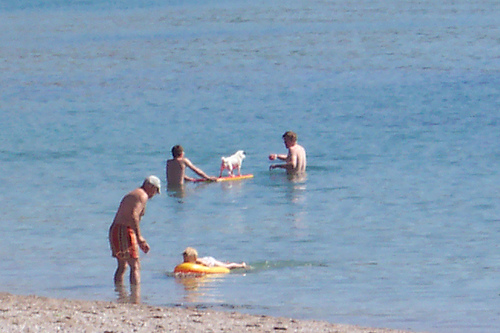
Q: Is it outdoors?
A: Yes, it is outdoors.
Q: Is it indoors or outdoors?
A: It is outdoors.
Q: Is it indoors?
A: No, it is outdoors.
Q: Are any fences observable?
A: No, there are no fences.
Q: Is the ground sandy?
A: Yes, the ground is sandy.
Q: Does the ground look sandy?
A: Yes, the ground is sandy.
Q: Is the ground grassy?
A: No, the ground is sandy.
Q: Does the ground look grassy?
A: No, the ground is sandy.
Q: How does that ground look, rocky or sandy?
A: The ground is sandy.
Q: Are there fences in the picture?
A: No, there are no fences.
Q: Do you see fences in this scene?
A: No, there are no fences.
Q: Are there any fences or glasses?
A: No, there are no fences or glasses.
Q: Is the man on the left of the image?
A: Yes, the man is on the left of the image.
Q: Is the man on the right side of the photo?
A: No, the man is on the left of the image.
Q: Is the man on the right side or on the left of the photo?
A: The man is on the left of the image.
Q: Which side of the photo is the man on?
A: The man is on the left of the image.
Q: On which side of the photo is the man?
A: The man is on the left of the image.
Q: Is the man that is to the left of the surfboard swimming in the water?
A: Yes, the man is swimming in the water.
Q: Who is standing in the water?
A: The man is standing in the water.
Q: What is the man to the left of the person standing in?
A: The man is standing in the water.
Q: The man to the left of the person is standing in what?
A: The man is standing in the water.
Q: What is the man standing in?
A: The man is standing in the water.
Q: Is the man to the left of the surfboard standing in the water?
A: Yes, the man is standing in the water.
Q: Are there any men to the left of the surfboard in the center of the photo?
A: Yes, there is a man to the left of the surfboard.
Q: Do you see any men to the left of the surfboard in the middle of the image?
A: Yes, there is a man to the left of the surfboard.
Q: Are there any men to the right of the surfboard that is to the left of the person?
A: No, the man is to the left of the surfboard.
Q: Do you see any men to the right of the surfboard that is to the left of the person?
A: No, the man is to the left of the surfboard.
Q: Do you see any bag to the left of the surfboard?
A: No, there is a man to the left of the surfboard.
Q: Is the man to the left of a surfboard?
A: Yes, the man is to the left of a surfboard.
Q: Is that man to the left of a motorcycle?
A: No, the man is to the left of a surfboard.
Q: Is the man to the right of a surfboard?
A: No, the man is to the left of a surfboard.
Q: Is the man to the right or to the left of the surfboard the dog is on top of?
A: The man is to the left of the surfboard.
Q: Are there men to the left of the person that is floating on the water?
A: Yes, there is a man to the left of the person.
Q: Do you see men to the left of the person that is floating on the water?
A: Yes, there is a man to the left of the person.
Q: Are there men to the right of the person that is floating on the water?
A: No, the man is to the left of the person.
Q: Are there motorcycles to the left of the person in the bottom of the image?
A: No, there is a man to the left of the person.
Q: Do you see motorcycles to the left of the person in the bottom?
A: No, there is a man to the left of the person.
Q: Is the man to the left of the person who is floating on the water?
A: Yes, the man is to the left of the person.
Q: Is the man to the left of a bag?
A: No, the man is to the left of the person.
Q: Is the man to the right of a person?
A: No, the man is to the left of a person.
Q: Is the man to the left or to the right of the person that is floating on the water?
A: The man is to the left of the person.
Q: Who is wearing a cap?
A: The man is wearing a cap.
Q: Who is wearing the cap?
A: The man is wearing a cap.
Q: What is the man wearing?
A: The man is wearing a cap.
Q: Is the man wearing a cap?
A: Yes, the man is wearing a cap.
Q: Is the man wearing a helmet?
A: No, the man is wearing a cap.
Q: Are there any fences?
A: No, there are no fences.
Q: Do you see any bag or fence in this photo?
A: No, there are no fences or bags.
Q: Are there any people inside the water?
A: Yes, there is a person inside the water.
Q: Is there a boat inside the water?
A: No, there is a person inside the water.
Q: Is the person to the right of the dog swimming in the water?
A: Yes, the person is swimming in the water.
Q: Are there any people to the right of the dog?
A: Yes, there is a person to the right of the dog.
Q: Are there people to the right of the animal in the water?
A: Yes, there is a person to the right of the dog.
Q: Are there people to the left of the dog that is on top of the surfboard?
A: No, the person is to the right of the dog.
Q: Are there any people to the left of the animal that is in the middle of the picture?
A: No, the person is to the right of the dog.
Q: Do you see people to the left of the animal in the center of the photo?
A: No, the person is to the right of the dog.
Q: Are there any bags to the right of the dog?
A: No, there is a person to the right of the dog.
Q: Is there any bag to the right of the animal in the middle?
A: No, there is a person to the right of the dog.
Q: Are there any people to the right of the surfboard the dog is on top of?
A: Yes, there is a person to the right of the surfboard.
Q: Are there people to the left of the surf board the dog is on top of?
A: No, the person is to the right of the surf board.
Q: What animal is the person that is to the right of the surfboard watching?
A: The person is watching the dog.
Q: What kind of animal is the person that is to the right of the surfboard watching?
A: The person is watching the dog.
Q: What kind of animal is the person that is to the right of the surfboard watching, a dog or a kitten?
A: The person is watching a dog.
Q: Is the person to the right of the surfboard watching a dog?
A: Yes, the person is watching a dog.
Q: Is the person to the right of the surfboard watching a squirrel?
A: No, the person is watching a dog.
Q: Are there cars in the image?
A: No, there are no cars.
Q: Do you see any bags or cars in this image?
A: No, there are no cars or bags.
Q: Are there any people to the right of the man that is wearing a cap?
A: Yes, there is a person to the right of the man.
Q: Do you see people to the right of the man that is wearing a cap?
A: Yes, there is a person to the right of the man.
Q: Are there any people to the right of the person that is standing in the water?
A: Yes, there is a person to the right of the man.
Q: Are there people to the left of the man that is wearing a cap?
A: No, the person is to the right of the man.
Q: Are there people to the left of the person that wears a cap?
A: No, the person is to the right of the man.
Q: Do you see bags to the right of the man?
A: No, there is a person to the right of the man.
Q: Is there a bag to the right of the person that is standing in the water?
A: No, there is a person to the right of the man.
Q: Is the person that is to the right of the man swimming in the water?
A: Yes, the person is swimming in the water.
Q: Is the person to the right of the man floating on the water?
A: Yes, the person is floating on the water.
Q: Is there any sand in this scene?
A: Yes, there is sand.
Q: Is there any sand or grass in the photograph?
A: Yes, there is sand.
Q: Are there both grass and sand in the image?
A: No, there is sand but no grass.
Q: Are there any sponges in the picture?
A: No, there are no sponges.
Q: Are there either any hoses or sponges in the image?
A: No, there are no sponges or hoses.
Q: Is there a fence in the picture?
A: No, there are no fences.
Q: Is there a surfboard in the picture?
A: Yes, there is a surfboard.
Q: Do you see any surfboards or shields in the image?
A: Yes, there is a surfboard.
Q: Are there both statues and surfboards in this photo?
A: No, there is a surfboard but no statues.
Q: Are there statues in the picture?
A: No, there are no statues.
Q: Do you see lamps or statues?
A: No, there are no statues or lamps.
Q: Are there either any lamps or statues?
A: No, there are no statues or lamps.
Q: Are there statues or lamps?
A: No, there are no statues or lamps.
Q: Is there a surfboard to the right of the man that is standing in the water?
A: Yes, there is a surfboard to the right of the man.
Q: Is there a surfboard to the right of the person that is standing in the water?
A: Yes, there is a surfboard to the right of the man.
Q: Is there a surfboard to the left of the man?
A: No, the surfboard is to the right of the man.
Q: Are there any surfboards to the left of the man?
A: No, the surfboard is to the right of the man.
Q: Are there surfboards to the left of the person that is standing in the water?
A: No, the surfboard is to the right of the man.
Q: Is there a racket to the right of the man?
A: No, there is a surfboard to the right of the man.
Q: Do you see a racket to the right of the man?
A: No, there is a surfboard to the right of the man.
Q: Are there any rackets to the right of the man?
A: No, there is a surfboard to the right of the man.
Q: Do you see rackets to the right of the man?
A: No, there is a surfboard to the right of the man.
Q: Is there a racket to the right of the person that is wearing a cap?
A: No, there is a surfboard to the right of the man.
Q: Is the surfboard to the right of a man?
A: Yes, the surfboard is to the right of a man.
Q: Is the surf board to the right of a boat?
A: No, the surf board is to the right of a man.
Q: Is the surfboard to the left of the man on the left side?
A: No, the surfboard is to the right of the man.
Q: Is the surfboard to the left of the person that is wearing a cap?
A: No, the surfboard is to the right of the man.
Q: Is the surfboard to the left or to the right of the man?
A: The surfboard is to the right of the man.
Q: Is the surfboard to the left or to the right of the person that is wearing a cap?
A: The surfboard is to the right of the man.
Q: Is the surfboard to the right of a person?
A: No, the surfboard is to the left of a person.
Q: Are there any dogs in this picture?
A: Yes, there is a dog.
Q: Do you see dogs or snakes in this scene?
A: Yes, there is a dog.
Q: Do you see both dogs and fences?
A: No, there is a dog but no fences.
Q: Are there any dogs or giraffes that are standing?
A: Yes, the dog is standing.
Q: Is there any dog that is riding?
A: Yes, there is a dog that is riding.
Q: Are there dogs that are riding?
A: Yes, there is a dog that is riding.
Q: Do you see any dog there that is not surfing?
A: Yes, there is a dog that is riding .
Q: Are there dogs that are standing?
A: Yes, there is a dog that is standing.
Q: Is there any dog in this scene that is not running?
A: Yes, there is a dog that is standing.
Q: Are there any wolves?
A: No, there are no wolves.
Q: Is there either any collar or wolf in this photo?
A: No, there are no wolves or collars.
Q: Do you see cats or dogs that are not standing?
A: No, there is a dog but it is standing.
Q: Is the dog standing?
A: Yes, the dog is standing.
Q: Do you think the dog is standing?
A: Yes, the dog is standing.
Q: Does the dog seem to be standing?
A: Yes, the dog is standing.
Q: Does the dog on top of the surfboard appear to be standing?
A: Yes, the dog is standing.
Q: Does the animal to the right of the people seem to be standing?
A: Yes, the dog is standing.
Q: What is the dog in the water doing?
A: The dog is standing.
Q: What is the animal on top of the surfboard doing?
A: The dog is standing.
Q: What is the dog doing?
A: The dog is standing.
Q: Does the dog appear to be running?
A: No, the dog is standing.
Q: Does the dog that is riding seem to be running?
A: No, the dog is standing.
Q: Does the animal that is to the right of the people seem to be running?
A: No, the dog is standing.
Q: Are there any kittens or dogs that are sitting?
A: No, there is a dog but it is standing.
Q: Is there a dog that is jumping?
A: No, there is a dog but it is standing.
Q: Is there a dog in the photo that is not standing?
A: No, there is a dog but it is standing.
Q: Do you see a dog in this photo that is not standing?
A: No, there is a dog but it is standing.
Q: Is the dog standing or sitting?
A: The dog is standing.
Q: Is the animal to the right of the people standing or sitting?
A: The dog is standing.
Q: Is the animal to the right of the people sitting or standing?
A: The dog is standing.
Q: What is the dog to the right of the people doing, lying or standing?
A: The dog is standing.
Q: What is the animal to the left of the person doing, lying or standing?
A: The dog is standing.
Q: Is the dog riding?
A: Yes, the dog is riding.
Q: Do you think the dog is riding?
A: Yes, the dog is riding.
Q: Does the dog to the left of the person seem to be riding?
A: Yes, the dog is riding.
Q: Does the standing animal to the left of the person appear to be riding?
A: Yes, the dog is riding.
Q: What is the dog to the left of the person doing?
A: The dog is riding.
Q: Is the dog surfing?
A: No, the dog is riding.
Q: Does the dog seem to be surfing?
A: No, the dog is riding.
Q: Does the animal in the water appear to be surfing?
A: No, the dog is riding.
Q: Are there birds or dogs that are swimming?
A: No, there is a dog but it is riding.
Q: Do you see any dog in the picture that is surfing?
A: No, there is a dog but it is riding.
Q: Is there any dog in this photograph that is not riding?
A: No, there is a dog but it is riding.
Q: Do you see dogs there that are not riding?
A: No, there is a dog but it is riding.